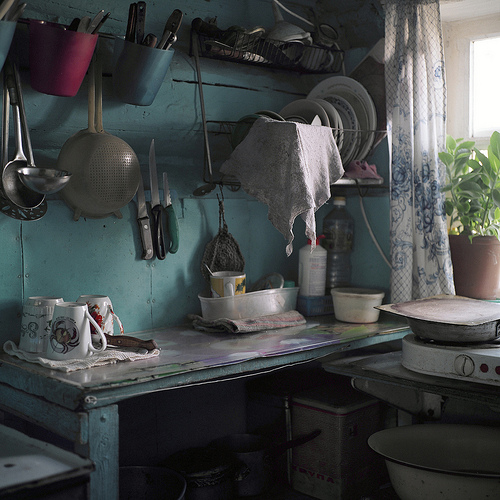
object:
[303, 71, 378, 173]
plates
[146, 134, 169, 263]
knifes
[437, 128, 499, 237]
plant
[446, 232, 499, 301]
pot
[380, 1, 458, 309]
curtain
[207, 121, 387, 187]
rack